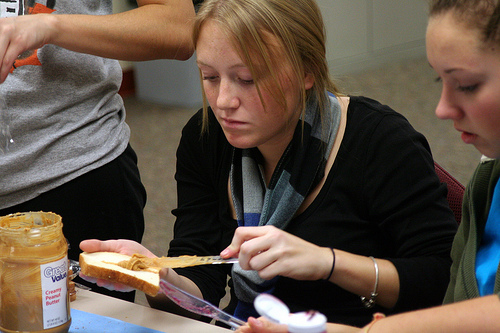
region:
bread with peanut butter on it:
[73, 247, 165, 297]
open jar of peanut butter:
[1, 209, 73, 331]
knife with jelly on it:
[156, 277, 248, 329]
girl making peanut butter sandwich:
[78, 2, 450, 332]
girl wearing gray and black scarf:
[218, 81, 343, 327]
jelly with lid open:
[251, 287, 326, 331]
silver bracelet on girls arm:
[361, 252, 381, 314]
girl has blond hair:
[189, 0, 345, 140]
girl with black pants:
[0, 139, 148, 308]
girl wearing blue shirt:
[471, 179, 498, 297]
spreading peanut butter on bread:
[77, 224, 207, 304]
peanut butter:
[7, 210, 82, 331]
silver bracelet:
[350, 250, 395, 315]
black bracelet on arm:
[312, 236, 347, 291]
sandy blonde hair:
[175, 2, 340, 157]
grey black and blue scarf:
[201, 147, 321, 222]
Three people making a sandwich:
[5, 5, 495, 291]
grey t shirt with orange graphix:
[6, 5, 111, 180]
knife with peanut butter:
[105, 253, 248, 271]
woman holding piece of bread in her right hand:
[75, 234, 160, 299]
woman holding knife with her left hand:
[137, 218, 310, 285]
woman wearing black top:
[160, 81, 452, 316]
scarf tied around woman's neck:
[215, 85, 338, 322]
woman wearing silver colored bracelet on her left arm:
[351, 242, 383, 315]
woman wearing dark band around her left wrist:
[317, 238, 342, 294]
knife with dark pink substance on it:
[154, 273, 231, 328]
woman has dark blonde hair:
[184, 0, 354, 147]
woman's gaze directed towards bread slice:
[82, 60, 263, 292]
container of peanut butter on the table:
[0, 236, 72, 323]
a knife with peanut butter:
[136, 255, 220, 265]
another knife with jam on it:
[155, 278, 232, 317]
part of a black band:
[325, 250, 332, 282]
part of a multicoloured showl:
[280, 130, 314, 216]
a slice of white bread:
[82, 256, 153, 293]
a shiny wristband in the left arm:
[373, 257, 380, 306]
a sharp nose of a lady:
[434, 99, 461, 122]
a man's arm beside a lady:
[48, 2, 178, 54]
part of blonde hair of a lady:
[247, 0, 280, 102]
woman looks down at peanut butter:
[196, 14, 310, 154]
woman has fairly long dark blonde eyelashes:
[198, 72, 256, 85]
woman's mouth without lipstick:
[213, 115, 250, 130]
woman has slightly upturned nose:
[429, 82, 466, 126]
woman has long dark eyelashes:
[432, 71, 481, 96]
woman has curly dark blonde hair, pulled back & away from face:
[422, 0, 499, 62]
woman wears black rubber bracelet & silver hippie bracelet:
[325, 242, 382, 312]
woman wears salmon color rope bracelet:
[360, 308, 390, 331]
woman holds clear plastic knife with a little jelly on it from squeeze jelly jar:
[155, 272, 329, 331]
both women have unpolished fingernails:
[212, 220, 307, 332]